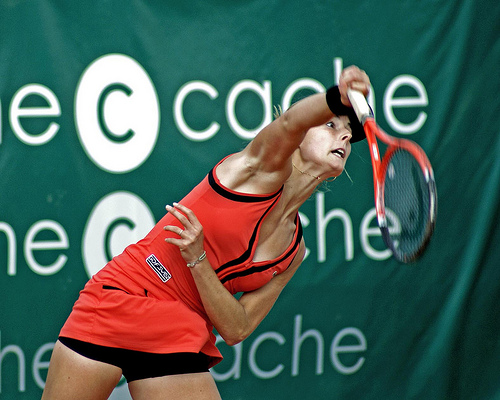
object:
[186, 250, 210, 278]
wrist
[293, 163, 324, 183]
necklace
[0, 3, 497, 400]
sign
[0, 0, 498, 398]
tarp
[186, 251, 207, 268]
bracelet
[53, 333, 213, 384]
shorts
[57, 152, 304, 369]
shirt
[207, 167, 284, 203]
trim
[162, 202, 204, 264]
left hand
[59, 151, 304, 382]
red black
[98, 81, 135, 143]
letter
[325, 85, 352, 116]
band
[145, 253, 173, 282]
logo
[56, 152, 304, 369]
orange shirt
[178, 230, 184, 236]
ring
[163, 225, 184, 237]
ring finger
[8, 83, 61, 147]
e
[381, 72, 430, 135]
e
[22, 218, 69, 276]
e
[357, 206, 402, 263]
e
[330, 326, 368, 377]
e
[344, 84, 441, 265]
racket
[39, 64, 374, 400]
player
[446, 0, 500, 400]
green backdrop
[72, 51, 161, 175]
circle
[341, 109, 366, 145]
hat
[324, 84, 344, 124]
wrist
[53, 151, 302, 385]
outfit